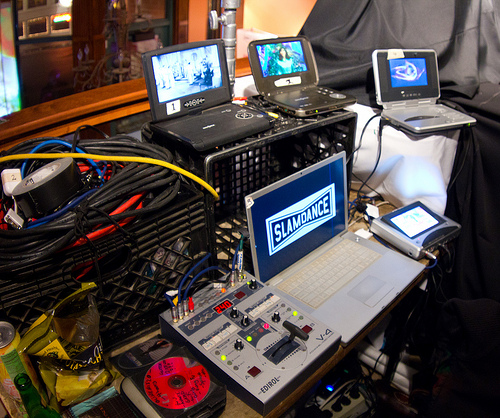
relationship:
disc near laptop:
[126, 350, 211, 417] [193, 122, 421, 357]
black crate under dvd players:
[144, 97, 356, 216] [141, 35, 357, 151]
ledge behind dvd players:
[4, 61, 223, 146] [134, 32, 353, 157]